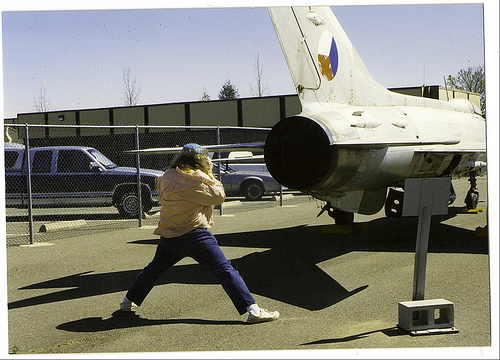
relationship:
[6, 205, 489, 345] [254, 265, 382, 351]
shadow on ground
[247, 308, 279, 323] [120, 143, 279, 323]
shoe on blonde person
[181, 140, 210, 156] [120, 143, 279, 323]
hat on blonde person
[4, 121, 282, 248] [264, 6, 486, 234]
fence near jet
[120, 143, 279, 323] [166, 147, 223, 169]
blonde person with hair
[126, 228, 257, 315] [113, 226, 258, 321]
jeans are jeans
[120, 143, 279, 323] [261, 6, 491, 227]
blonde person behind plane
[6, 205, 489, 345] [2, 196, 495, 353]
shadow on ground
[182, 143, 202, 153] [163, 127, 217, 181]
hat on head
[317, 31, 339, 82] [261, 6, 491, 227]
emblem on plane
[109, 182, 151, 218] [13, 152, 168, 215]
tire on car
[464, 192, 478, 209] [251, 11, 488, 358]
airplane wheel on plane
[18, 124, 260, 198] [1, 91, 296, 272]
car in parking lot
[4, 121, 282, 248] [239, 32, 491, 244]
fence near plane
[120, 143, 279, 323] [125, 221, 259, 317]
blonde person wears pants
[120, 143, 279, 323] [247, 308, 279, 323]
blonde person wears shoe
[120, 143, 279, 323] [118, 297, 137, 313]
blonde person wears sneakers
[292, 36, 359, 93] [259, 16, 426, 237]
emblem on tail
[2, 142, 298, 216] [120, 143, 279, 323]
car with blonde person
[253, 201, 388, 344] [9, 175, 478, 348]
shadow on ground